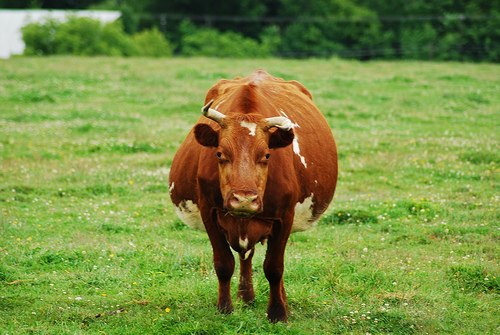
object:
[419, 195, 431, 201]
yellow flower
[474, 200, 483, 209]
yellow flower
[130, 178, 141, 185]
yellow flower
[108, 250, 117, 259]
yellow flower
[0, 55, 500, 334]
ground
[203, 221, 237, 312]
legs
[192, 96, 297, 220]
head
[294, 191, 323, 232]
white spot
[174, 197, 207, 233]
white spot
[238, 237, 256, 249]
white spot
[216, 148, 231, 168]
eye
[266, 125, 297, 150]
ear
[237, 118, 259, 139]
spot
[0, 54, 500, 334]
grass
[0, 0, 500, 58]
fence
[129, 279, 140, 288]
flower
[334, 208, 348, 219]
flower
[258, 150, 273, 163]
eye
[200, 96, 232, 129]
horn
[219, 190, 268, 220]
snout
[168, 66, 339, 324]
bull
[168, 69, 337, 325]
cow/field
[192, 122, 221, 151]
ear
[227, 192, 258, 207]
nose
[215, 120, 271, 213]
face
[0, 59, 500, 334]
field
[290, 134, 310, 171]
spot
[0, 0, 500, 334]
background